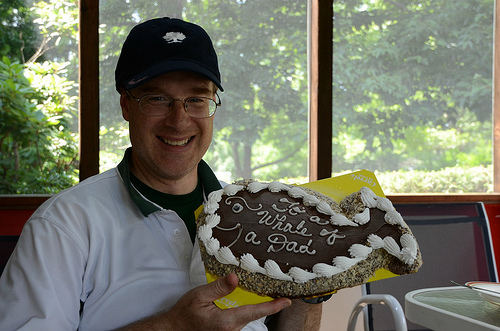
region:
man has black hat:
[125, 25, 210, 97]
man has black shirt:
[110, 158, 192, 233]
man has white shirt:
[31, 174, 278, 328]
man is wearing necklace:
[107, 161, 199, 251]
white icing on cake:
[208, 178, 426, 265]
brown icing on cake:
[191, 175, 382, 279]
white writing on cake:
[188, 183, 335, 287]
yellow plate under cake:
[188, 165, 363, 322]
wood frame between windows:
[0, 1, 408, 191]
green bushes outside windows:
[1, 8, 71, 162]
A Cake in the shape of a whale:
[171, 166, 428, 312]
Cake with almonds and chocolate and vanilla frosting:
[192, 178, 425, 298]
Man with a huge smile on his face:
[108, 26, 232, 188]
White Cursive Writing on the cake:
[239, 188, 349, 268]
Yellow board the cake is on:
[179, 163, 421, 312]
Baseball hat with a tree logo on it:
[108, 26, 242, 96]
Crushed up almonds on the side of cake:
[195, 180, 420, 303]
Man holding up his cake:
[0, 14, 422, 329]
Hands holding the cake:
[162, 193, 339, 330]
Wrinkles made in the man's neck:
[121, 145, 203, 202]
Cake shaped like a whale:
[191, 175, 422, 300]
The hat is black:
[107, 13, 234, 97]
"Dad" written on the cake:
[262, 228, 318, 264]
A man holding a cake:
[1, 12, 428, 329]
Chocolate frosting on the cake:
[202, 180, 405, 271]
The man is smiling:
[111, 15, 227, 183]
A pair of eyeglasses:
[124, 84, 224, 123]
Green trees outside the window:
[1, 0, 494, 195]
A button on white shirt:
[166, 220, 186, 244]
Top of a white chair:
[340, 289, 411, 329]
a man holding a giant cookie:
[11, 19, 424, 329]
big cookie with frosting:
[201, 177, 421, 287]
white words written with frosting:
[221, 189, 344, 264]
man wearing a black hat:
[110, 16, 222, 177]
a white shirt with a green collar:
[4, 143, 262, 326]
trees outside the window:
[214, 12, 304, 180]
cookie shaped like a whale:
[194, 166, 422, 299]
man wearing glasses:
[116, 18, 219, 179]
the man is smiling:
[110, 15, 225, 183]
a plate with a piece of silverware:
[451, 271, 498, 299]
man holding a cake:
[5, 9, 440, 325]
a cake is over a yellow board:
[183, 163, 430, 315]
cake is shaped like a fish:
[193, 167, 424, 297]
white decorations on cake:
[187, 169, 424, 305]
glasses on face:
[118, 84, 225, 121]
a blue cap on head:
[106, 13, 229, 101]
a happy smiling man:
[70, 8, 270, 224]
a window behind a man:
[0, 3, 499, 223]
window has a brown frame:
[0, 0, 499, 217]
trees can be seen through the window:
[3, 7, 493, 199]